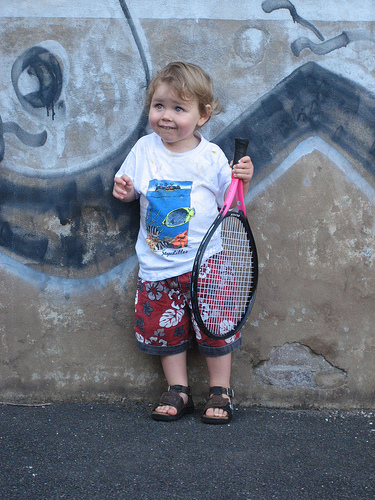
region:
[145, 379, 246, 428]
brown color cheppal of the baby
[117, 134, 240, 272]
a baby wearing white color t-shirt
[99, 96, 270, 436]
a baby is standing near the wall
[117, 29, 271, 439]
baby standing in the corner of the road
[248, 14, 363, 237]
some paintings in the wall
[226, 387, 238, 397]
bugles in the cheppal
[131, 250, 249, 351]
a baby wearing printed shorts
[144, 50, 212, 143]
head of the baby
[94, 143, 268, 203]
baby holding pink with blackcolor handle tennis racket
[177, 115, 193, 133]
part of a cheel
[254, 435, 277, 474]
part of a floor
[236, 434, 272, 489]
part of a floor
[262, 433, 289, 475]
part of a floor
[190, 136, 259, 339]
pink and black child's tennis racket held by a small child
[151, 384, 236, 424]
pair of brown sandals on a small child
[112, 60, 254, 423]
small child with blue eyes standing near a wall holding a tennis racket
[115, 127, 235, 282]
white T-shirt with fish printed on the front of the shirt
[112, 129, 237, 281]
small shirt worn by a child standing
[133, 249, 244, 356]
shorts with a floral pattern worn by a young child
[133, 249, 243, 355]
long shorts with red, white, and black colors worn by a child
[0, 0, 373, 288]
graffiti painted on a wall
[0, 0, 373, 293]
portion of a wall painted with white and black spray paint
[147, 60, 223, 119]
fine, dark blonde hair on top of a child's head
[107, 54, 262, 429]
A boy in the foreground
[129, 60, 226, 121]
Young boy has blonde hair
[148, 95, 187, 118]
Young boy has blue colored eyes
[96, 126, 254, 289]
Young boy is wearing a tshirt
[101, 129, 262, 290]
The tshirt is white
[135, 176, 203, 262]
Artwork is on the front of the tshirt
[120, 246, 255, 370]
Young boy is wearing red shorts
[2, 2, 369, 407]
A wall in the background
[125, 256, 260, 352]
Shorts have a white flower design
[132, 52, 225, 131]
Young boy's hair is short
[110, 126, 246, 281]
boy wearing white shirt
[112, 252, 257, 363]
boy wearing flowered shorts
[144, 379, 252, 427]
boy wearing brown sandals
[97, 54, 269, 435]
Boy standing on concrete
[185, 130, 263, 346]
Boy holding pink racket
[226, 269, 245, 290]
White strings on a racket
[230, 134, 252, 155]
Black handle on a racket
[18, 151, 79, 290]
Tan, white and black paint on a wall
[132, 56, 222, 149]
Young boy looking to his left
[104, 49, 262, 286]
Young boy standing against a wall